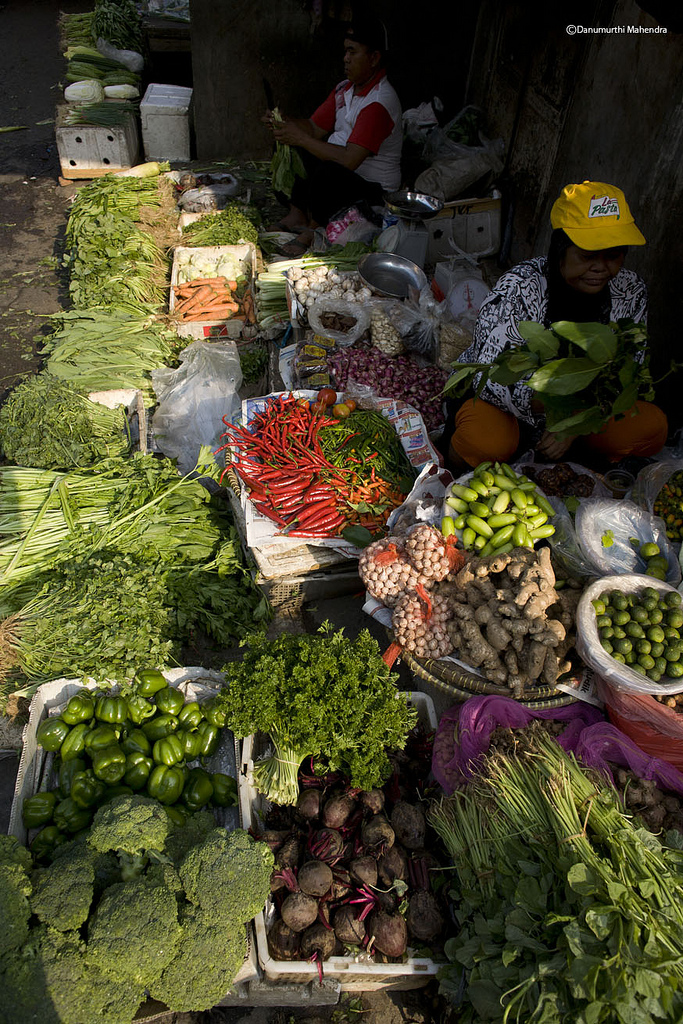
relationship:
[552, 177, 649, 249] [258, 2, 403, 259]
yellow hat on man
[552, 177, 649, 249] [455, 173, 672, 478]
yellow hat on person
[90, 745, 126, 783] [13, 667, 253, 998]
green pepper in tub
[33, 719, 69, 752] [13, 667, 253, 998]
green pepper in tub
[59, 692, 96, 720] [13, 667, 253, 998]
green pepper in tub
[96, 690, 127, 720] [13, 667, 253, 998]
green pepper in tub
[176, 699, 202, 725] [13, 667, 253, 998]
green pepper in tub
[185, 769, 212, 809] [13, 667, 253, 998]
green pepper in tub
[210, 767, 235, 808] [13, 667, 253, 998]
green pepper in tub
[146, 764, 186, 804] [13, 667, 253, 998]
green pepper in tub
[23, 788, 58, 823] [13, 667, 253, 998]
green pepper in tub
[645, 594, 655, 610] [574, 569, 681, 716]
green lime in basket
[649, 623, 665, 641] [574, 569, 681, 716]
green lime in basket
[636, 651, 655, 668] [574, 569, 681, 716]
green lime in basket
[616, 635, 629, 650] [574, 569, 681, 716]
green lime in basket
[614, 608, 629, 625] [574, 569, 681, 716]
green lime in basket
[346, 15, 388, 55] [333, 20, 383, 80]
hat on head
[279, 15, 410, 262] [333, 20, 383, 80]
man has head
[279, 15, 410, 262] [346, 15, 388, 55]
man has hat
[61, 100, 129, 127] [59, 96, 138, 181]
green onions on box